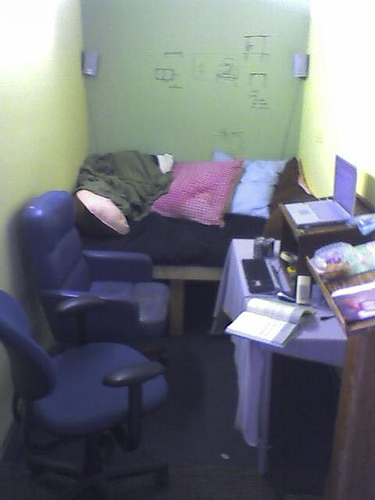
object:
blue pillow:
[228, 155, 289, 221]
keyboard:
[240, 255, 276, 297]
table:
[209, 235, 349, 475]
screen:
[331, 154, 357, 215]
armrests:
[54, 294, 107, 345]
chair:
[1, 289, 172, 495]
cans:
[251, 235, 267, 262]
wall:
[79, 0, 310, 165]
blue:
[54, 205, 66, 223]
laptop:
[284, 154, 359, 229]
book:
[224, 294, 320, 353]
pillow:
[150, 158, 247, 230]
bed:
[68, 149, 316, 270]